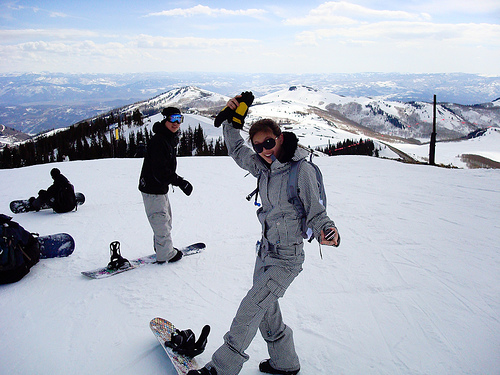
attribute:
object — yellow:
[214, 90, 253, 130]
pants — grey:
[140, 190, 177, 262]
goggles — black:
[249, 134, 277, 154]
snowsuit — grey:
[211, 117, 331, 370]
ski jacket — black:
[130, 120, 187, 195]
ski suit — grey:
[220, 143, 323, 372]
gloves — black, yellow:
[217, 94, 258, 135]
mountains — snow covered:
[4, 72, 496, 373]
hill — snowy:
[4, 152, 494, 373]